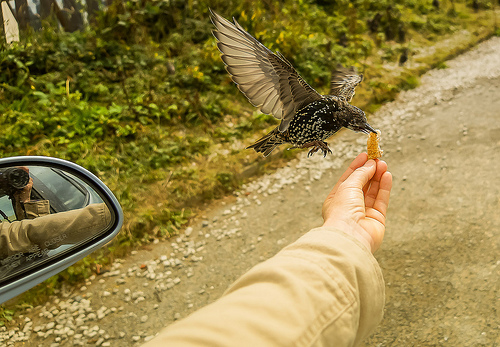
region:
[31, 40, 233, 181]
The grass on the side of the road is green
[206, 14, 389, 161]
The bird eating a piece of bread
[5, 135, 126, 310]
The rear view mirror is gray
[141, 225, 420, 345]
The jacket on the man is beige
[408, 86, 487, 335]
The street is gray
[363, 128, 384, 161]
A piece of bread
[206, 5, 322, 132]
The wing of a bird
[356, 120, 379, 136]
The beak of a bird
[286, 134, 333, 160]
The claws of the bird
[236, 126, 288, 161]
The tail of the bird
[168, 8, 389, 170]
Bird with gray feathers swooping to grab food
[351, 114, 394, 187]
Bit of orange food being held by a person as a bird grabs it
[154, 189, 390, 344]
Khaki colored sleeve of a person's jacket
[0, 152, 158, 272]
Gray rear view mirror of a car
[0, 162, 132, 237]
Reflection of a person reaching out a window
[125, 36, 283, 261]
Thick green grass and shrubbery along the road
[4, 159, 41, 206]
Reflection of a black camera being held by a person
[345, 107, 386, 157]
Head and beak of a gray bird grabbing food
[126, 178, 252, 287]
Gray pebbles along the side of the road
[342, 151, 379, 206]
A person's pink thumb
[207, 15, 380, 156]
Brown and white speckled bird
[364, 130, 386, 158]
small yellow chip in persons hand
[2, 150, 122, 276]
silver rear view mirrow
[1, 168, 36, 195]
camera in rear view mirror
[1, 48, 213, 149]
grass on side of the road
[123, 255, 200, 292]
small white pebbles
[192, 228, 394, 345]
tan jacket sleeve on arm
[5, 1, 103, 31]
trees in background of photo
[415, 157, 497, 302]
gray colored road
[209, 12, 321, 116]
Wing of bird in flight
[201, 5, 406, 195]
Bird taking food from outstrecthed hand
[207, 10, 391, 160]
Wings spread going in for the grab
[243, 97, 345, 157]
Speckled feathers on breast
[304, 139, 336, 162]
Small tallons dangling in the air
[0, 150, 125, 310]
Reflection of photographer in the sideview mirror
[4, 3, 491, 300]
Lots of greenery on the side of the road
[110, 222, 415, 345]
Wearing a long sleeve tan jacket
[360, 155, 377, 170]
Well groomed thumb nail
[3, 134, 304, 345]
Lots of pebbles strewn on the side of the street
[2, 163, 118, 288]
Hanging out of the car to feed the bird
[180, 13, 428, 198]
bird taking food from mans hand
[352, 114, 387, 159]
small bird beak grabbing food from man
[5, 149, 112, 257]
mans refelction taking a picture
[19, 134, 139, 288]
car window with reflection in it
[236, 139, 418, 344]
arm of someone feeding a bird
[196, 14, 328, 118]
outstretched bird wings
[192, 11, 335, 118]
multiple shades of brown bird wing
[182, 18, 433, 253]
bird swooping down taking treat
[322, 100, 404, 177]
bird accepting treat from human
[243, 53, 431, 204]
bird flying in for a treat